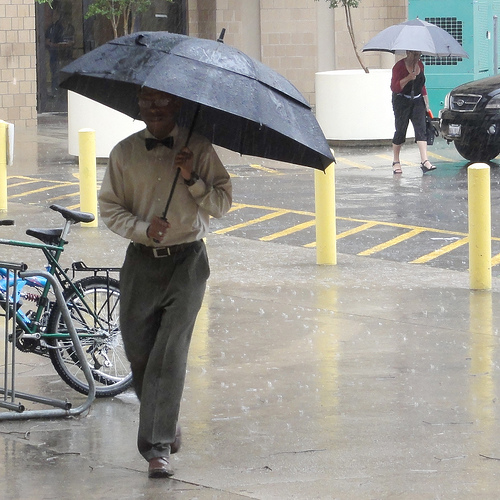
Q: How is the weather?
A: Raining.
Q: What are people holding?
A: Umbrellas.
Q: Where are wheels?
A: On bicycles.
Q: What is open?
A: Umbrellas.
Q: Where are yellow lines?
A: On the ground.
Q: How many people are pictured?
A: Two.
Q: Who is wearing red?
A: Woman in background.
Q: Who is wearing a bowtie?
A: The man.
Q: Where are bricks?
A: On a building.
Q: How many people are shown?
A: 2.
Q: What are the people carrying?
A: Umbrellas.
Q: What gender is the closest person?
A: Male.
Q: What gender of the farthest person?
A: Female.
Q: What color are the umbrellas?
A: Black and gray.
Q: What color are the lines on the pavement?
A: Yellow.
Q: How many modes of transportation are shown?
A: 2.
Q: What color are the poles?
A: Yellow.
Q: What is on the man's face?
A: Glasses.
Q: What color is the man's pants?
A: Gray.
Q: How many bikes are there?
A: Two.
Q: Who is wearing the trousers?
A: The man with the umbrella.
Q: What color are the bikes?
A: Blue.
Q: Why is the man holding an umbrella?
A: It's raining.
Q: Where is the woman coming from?
A: Building.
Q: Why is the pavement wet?
A: It's raining.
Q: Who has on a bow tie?
A: A man.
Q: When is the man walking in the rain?
A: Now.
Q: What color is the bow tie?
A: Black.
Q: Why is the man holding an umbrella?
A: It is raining.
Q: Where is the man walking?
A: Up the street.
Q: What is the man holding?
A: An umbrella.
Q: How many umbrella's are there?
A: One.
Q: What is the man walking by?
A: Bikes.